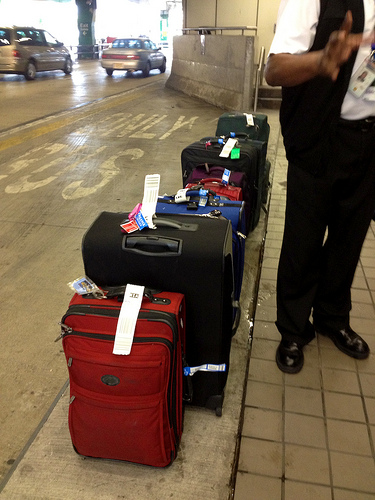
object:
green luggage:
[216, 112, 270, 141]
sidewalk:
[0, 61, 373, 499]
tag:
[113, 283, 145, 355]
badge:
[353, 87, 357, 92]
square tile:
[284, 412, 327, 449]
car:
[98, 37, 166, 78]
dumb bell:
[60, 113, 272, 467]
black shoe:
[276, 335, 304, 374]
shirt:
[267, 1, 375, 121]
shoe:
[316, 325, 370, 360]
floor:
[234, 132, 375, 500]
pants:
[275, 99, 375, 348]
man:
[261, 0, 374, 377]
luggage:
[53, 113, 272, 468]